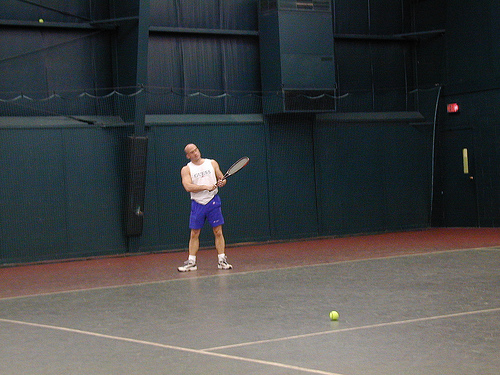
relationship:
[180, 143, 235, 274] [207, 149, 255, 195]
man inspecting racquet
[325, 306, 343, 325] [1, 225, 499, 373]
ball on ground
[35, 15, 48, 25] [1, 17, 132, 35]
ball on top of a ledge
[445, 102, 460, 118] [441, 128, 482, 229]
sign above door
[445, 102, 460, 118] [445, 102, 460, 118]
sign says sign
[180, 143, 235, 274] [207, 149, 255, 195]
man holding racquet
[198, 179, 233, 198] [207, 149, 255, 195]
hands holding racquet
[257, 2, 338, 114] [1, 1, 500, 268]
vent on a wall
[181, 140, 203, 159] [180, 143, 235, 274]
bald headed man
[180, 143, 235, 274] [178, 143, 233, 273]
man playing man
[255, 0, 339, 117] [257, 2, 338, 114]
green ventilation system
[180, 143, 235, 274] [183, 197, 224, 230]
man in shorts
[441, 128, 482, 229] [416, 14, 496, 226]
door on a wall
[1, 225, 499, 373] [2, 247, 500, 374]
lines boundary lines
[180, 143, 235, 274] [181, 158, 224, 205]
man in a shirt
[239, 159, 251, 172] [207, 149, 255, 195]
red on racquet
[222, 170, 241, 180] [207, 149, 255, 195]
black on racquet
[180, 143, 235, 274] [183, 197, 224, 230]
man wearing shorts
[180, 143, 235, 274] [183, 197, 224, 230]
male wearing shorts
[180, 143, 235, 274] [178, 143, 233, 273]
male playing man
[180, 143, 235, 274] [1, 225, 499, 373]
man standing on court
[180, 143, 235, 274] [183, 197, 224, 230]
person in shorts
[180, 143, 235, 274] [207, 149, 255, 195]
athlete holding racquet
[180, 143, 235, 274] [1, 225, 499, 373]
athlete on a court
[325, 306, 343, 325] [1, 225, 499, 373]
green on a court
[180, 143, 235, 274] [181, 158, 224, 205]
athlete wearing white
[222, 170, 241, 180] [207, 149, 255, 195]
black ten racquet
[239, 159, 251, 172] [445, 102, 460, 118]
red exit sign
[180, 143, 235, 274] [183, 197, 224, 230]
man wearing purple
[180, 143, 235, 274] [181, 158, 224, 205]
man wearing white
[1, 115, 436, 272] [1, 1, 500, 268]
foam padded wall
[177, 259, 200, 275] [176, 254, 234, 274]
white ten shoes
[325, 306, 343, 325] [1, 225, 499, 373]
ball on court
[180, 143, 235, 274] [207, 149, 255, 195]
man looking at racquet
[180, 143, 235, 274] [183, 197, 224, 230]
man wearing blue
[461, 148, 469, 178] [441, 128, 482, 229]
window on door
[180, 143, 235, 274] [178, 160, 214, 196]
man has arm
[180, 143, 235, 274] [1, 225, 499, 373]
man on a court